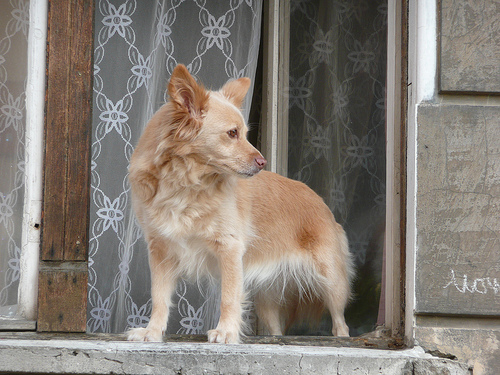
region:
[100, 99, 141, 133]
white flower on curtain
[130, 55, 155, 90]
white flower on curtain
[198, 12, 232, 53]
white flower on curtain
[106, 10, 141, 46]
white flower on curtain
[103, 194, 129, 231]
white flower on curtain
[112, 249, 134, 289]
white flower on curtain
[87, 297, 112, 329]
white flower on curtain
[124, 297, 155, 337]
white flower on curtain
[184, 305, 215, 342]
white flower on curtain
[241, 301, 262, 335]
white flower on curtain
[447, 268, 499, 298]
White writing on wall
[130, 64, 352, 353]
Small tan dog on windowsill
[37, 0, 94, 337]
Tall dark brown wooden beam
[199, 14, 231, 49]
White flower design on curtain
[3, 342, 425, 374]
Cement ledge on window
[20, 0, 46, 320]
White edging near wooden beam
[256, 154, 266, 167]
Small brown nose on dog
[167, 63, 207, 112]
Fluffy ear on dog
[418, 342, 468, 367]
Crack in cement on wall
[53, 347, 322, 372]
Cracks on cement window ledge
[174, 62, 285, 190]
face of the dog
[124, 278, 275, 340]
front two legs of dog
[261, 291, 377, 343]
back two legs of dog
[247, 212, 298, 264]
fur of the dog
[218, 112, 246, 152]
eye of the dog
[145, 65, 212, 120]
ear of the dog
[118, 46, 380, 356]
a dog in the floor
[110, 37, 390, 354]
a dog turning its face ahead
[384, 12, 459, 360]
a part of the door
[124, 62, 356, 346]
red and white dog standing in the window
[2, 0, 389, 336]
white lace curtain in window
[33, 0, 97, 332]
dark wood panel dividing windows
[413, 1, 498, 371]
gray brick siding on building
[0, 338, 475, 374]
gray cement ledge outside window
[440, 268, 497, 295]
white chalk writing on gray brick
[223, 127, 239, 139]
red dog's right eye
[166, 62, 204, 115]
red dog's right ear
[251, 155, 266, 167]
small red dog's nose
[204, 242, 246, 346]
red dog's left front leg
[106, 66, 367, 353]
dog standing in the window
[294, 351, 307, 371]
crack in the concrete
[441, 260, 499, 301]
white graffiti on the wall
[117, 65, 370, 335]
long, blonde hair on the dog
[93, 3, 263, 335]
curtains in the window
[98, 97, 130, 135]
white flower design on the curtain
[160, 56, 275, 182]
head is turned to the side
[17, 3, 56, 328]
white pole running along the wooden post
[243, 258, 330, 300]
white hair hanging off the belly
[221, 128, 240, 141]
eye on the side of the head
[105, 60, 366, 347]
dog in a window sill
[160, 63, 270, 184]
head of a dog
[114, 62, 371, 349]
brown and white colored dog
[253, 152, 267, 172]
nose of a dog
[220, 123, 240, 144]
right eye of a dog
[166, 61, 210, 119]
right ear of a dog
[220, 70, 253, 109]
left ear of a dog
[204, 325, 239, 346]
left front paw of a dog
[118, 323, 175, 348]
right front paw of a dog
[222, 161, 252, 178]
mouth of a dog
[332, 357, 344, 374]
black crack in concrete